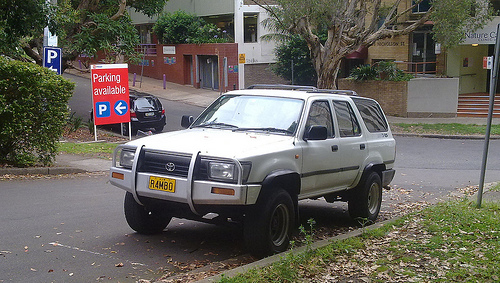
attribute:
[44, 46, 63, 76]
square — blue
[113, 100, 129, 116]
arrow — white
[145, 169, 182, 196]
plate — yellow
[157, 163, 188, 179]
emblem — silver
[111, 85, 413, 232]
vehicle — white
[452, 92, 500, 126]
steps — red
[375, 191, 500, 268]
grass — short, green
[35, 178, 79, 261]
road — cement, paved, black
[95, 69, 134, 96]
text — white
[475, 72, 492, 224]
pole — metal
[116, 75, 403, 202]
suv — white, parked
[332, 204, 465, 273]
leaves — brown, dried, piled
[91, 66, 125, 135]
sign — red, parking available, white, here, blue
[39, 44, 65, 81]
sign — blue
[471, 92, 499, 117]
stair — brown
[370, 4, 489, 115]
building — brown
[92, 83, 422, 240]
truck — white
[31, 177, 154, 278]
street — paved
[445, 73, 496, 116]
staircase — red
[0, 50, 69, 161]
bush — green